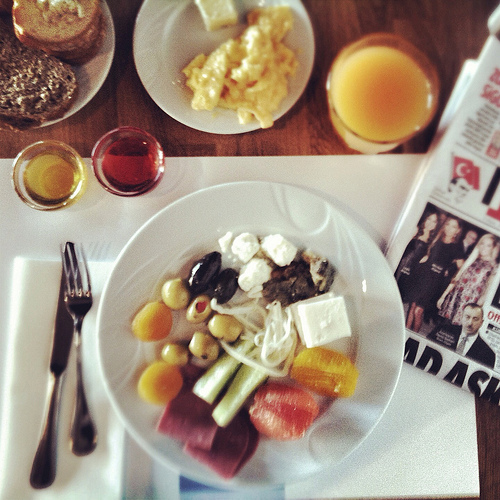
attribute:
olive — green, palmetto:
[162, 279, 189, 310]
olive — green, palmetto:
[187, 290, 210, 323]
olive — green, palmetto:
[209, 312, 241, 342]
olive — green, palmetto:
[184, 330, 219, 360]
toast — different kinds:
[4, 4, 121, 151]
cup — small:
[90, 125, 167, 195]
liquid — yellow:
[17, 153, 83, 205]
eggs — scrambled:
[179, 0, 307, 134]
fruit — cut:
[135, 250, 362, 477]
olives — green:
[165, 252, 245, 344]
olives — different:
[178, 265, 223, 360]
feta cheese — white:
[175, 263, 436, 400]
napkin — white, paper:
[1, 256, 115, 498]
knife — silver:
[29, 243, 79, 491]